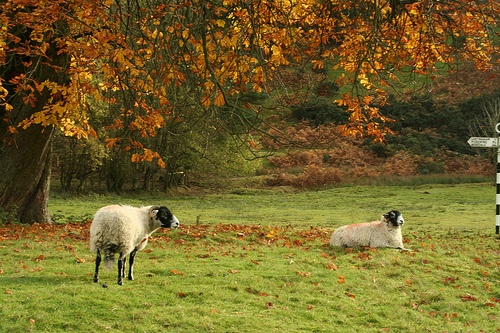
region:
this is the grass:
[199, 265, 258, 305]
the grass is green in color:
[71, 287, 128, 316]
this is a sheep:
[86, 197, 183, 284]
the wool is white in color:
[99, 208, 133, 240]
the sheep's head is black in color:
[153, 204, 183, 233]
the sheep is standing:
[79, 197, 181, 283]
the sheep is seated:
[328, 210, 411, 251]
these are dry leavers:
[190, 224, 297, 249]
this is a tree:
[13, 1, 60, 206]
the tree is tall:
[1, 8, 48, 217]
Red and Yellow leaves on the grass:
[197, 219, 302, 249]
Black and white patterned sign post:
[491, 147, 498, 238]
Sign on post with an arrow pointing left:
[457, 132, 497, 147]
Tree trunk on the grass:
[1, 120, 58, 225]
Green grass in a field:
[62, 296, 234, 326]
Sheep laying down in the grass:
[325, 203, 416, 255]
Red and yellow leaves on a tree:
[0, 0, 495, 80]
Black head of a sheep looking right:
[151, 202, 181, 230]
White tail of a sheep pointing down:
[103, 237, 119, 272]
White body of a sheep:
[91, 204, 148, 244]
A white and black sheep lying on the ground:
[331, 209, 408, 250]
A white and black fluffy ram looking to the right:
[88, 201, 179, 285]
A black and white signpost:
[466, 122, 498, 234]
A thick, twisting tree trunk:
[0, 0, 76, 227]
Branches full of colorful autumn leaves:
[0, 0, 499, 166]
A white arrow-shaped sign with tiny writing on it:
[467, 135, 499, 148]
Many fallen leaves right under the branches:
[1, 212, 327, 250]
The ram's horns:
[147, 203, 162, 218]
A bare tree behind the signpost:
[468, 96, 498, 166]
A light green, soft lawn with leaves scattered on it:
[0, 177, 496, 332]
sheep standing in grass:
[51, 161, 193, 299]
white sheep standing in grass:
[52, 181, 222, 297]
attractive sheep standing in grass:
[45, 175, 222, 313]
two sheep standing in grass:
[30, 158, 449, 305]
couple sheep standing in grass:
[71, 143, 440, 303]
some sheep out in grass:
[58, 136, 470, 307]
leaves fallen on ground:
[184, 216, 304, 260]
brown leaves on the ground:
[184, 216, 303, 253]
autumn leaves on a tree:
[15, 4, 465, 154]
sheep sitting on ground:
[305, 192, 439, 263]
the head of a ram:
[143, 197, 183, 233]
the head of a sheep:
[380, 205, 405, 226]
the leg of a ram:
[111, 250, 126, 285]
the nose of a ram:
[173, 217, 181, 228]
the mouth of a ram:
[170, 223, 179, 229]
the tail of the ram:
[99, 239, 116, 273]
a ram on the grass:
[81, 200, 181, 290]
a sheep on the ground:
[321, 205, 416, 255]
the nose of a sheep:
[397, 215, 404, 224]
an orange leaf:
[212, 90, 228, 110]